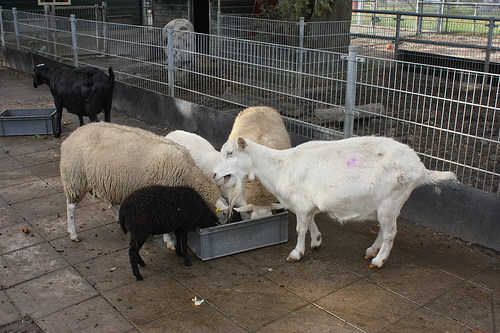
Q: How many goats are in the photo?
A: Five.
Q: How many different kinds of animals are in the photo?
A: Two.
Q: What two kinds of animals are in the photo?
A: Goats and one pig.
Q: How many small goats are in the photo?
A: One.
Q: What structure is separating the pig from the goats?
A: Metal fence.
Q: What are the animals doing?
A: Eating.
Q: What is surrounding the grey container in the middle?
A: Four goats.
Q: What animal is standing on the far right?
A: White goat.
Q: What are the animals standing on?
A: Dirty floor.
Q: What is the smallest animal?
A: Black goat.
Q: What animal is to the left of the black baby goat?
A: Beige goat.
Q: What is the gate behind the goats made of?
A: Metal.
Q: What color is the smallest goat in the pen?
A: Black.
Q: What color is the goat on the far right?
A: White.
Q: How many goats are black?
A: Two.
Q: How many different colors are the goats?
A: Three.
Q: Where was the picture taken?
A: In the goat pen.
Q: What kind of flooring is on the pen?
A: Brown tiles.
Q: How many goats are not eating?
A: Two.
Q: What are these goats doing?
A: They are eating.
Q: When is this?
A: Daytime.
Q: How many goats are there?
A: Five.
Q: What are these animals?
A: Goats.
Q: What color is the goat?
A: White.